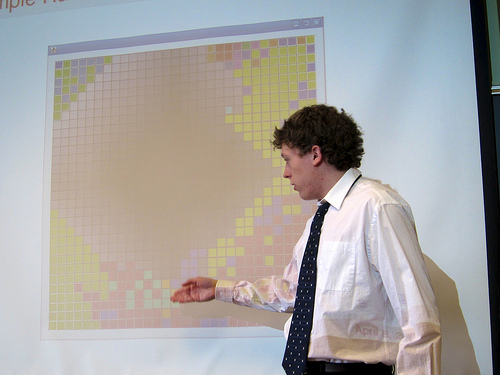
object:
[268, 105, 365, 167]
hair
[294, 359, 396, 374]
belt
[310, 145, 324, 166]
ear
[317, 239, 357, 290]
pocket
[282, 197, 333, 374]
tie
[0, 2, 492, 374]
white board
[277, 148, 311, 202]
face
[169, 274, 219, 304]
hand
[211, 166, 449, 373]
shirt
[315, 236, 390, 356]
words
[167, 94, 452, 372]
teacher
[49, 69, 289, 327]
picture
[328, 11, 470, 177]
wall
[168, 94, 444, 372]
man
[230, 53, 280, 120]
picture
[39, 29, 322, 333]
pixels